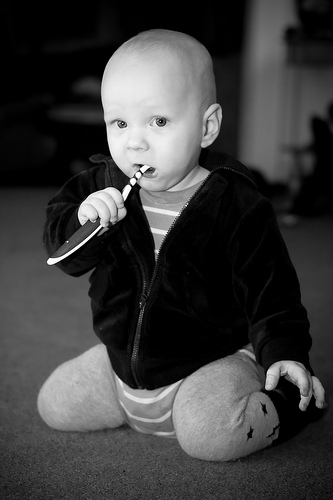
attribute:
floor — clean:
[6, 258, 332, 499]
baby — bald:
[34, 25, 325, 464]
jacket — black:
[39, 150, 319, 370]